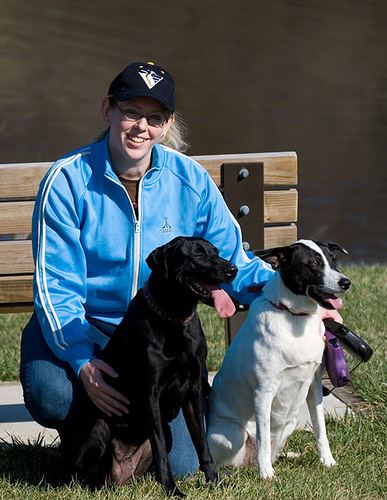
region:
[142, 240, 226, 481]
Dog with black fur sitting on it's hind feet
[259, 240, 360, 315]
Black dog with a white streak on it's snout and head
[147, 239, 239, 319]
Black dog sticking it's large pink tongue out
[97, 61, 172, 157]
Woman wearing a dark blue baseball hat with a white logo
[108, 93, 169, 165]
Woman with shadows on her face wearing glasses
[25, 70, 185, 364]
Woman wearing a light blue jacket with white stripes down the side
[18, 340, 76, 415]
Dark blue jeans on a person's leg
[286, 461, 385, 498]
Short green grass on the ground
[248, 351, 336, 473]
Legs and belly of a white colored dog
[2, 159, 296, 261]
Light wooden bench behind a woman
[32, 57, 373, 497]
Woman kneeling on ground with two dogs.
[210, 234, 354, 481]
White dog with black and white head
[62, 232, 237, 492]
Black dog to left of white dog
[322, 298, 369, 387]
Two dog leads in woman's left hand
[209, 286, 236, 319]
Dogs tongue hanging out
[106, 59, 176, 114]
Black cap on woman's head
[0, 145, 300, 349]
Wooden park bench behind woman and dogs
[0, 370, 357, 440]
Concrete patch on ground under the park bench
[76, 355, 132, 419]
Woman's right hand on black dog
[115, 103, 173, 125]
Glasses over woman's eyes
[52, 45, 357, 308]
a lady and two dogs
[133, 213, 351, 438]
these dogs are black and white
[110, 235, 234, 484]
the black dog has a hanging tongue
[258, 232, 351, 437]
the white dog is looking strait ahead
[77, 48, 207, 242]
this lady looks like she is happy with her pets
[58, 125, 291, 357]
she is holding her pets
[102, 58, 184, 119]
she is wearing a baseball cap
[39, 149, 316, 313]
the lady's jacket is light blue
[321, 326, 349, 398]
a purple object in the shot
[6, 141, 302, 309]
a wooden post behind the lady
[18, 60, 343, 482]
Woman wearing blue hat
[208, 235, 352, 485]
Black and white dog in front of woman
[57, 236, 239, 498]
Black dog in front of woman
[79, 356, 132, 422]
Hand touching black dog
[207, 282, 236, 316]
Long pink tongue sticking out of black dog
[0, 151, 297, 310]
Wooden bench behind woman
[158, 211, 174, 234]
Small logo on light blue jacket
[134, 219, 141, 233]
White zipper on light blue jacket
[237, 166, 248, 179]
Bolt on wooden bench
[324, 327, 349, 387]
Purple leash handle next to black and white dog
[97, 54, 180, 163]
the head of a woman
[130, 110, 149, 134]
the nose of a woman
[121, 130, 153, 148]
the mouth of a woman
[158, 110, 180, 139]
the ear of a woman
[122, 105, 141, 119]
the eye of a woman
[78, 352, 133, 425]
the hand of a woman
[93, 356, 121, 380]
the thumb of a woman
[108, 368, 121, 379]
the thumb nail of a woman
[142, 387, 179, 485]
the leg of a dog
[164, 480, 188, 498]
the paw of a dog